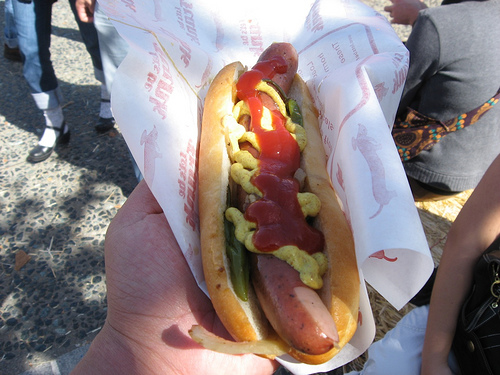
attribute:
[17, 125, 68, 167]
shoe — black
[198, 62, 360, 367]
bun — long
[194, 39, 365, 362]
hotdog — white and red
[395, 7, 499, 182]
sweater — grey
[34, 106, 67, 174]
shoe — black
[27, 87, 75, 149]
sock — white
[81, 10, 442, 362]
paper — white